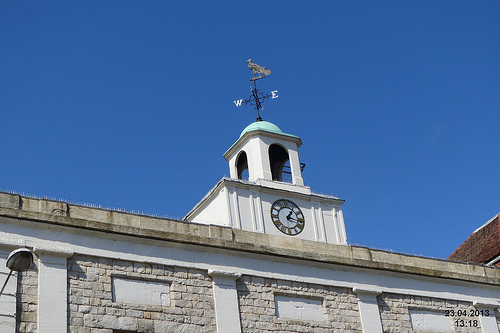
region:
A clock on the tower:
[271, 198, 306, 235]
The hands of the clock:
[286, 206, 303, 223]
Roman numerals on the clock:
[271, 198, 306, 234]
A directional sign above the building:
[235, 58, 279, 119]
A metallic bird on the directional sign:
[246, 58, 268, 76]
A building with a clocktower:
[5, 59, 499, 330]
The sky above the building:
[1, 1, 498, 259]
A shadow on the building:
[39, 248, 85, 278]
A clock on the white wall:
[186, 180, 345, 241]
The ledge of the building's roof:
[3, 193, 499, 286]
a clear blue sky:
[44, 51, 189, 211]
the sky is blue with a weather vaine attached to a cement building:
[8, 4, 495, 321]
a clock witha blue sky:
[143, 30, 418, 263]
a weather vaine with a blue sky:
[148, 28, 376, 243]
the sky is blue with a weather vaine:
[92, 27, 432, 292]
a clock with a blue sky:
[36, 60, 417, 330]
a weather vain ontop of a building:
[26, 26, 377, 327]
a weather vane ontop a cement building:
[88, 40, 423, 321]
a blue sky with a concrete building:
[63, 55, 423, 286]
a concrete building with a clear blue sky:
[29, 47, 384, 332]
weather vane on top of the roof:
[228, 51, 280, 119]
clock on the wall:
[266, 196, 307, 237]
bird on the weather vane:
[240, 56, 273, 81]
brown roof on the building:
[446, 210, 498, 263]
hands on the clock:
[283, 205, 300, 228]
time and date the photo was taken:
[443, 299, 490, 331]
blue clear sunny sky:
[342, 52, 419, 142]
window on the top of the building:
[264, 139, 295, 186]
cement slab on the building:
[67, 205, 159, 233]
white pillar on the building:
[208, 266, 245, 331]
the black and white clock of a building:
[265, 198, 302, 230]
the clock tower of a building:
[220, 124, 307, 182]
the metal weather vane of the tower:
[231, 50, 283, 115]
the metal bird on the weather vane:
[242, 54, 269, 75]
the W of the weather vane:
[232, 96, 243, 106]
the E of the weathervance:
[271, 88, 278, 98]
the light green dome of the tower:
[235, 120, 282, 135]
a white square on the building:
[110, 271, 170, 306]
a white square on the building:
[273, 290, 327, 321]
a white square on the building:
[407, 304, 460, 331]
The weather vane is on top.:
[221, 52, 280, 115]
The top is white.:
[175, 123, 366, 244]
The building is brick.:
[39, 256, 361, 332]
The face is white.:
[261, 194, 311, 235]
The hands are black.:
[271, 199, 311, 236]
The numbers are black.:
[259, 191, 314, 241]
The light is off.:
[3, 241, 32, 270]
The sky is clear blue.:
[4, 6, 491, 228]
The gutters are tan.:
[2, 188, 486, 284]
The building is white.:
[15, 220, 414, 332]